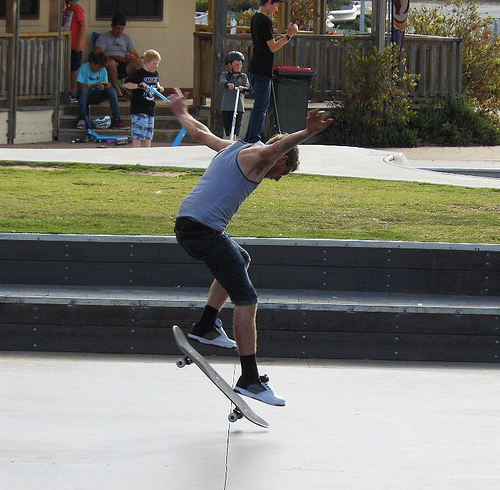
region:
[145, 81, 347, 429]
person on a skateboard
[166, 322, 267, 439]
skateboard made of wood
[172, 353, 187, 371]
a white skateboard wheel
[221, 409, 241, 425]
a white skateboard wheel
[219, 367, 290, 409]
black and white shoe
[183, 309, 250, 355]
black and white shoe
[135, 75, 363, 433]
person wearing grey tank top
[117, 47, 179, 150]
child with blonde hair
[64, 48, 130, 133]
child wearing blue shirt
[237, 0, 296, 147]
child wearing black shirt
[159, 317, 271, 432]
full sized black skateboard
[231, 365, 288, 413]
black and white skate shoes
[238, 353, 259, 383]
black mid length socks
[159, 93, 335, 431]
young man on a skateboard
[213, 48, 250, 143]
young boy with a scooter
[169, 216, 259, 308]
blue jean shorts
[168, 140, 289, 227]
light blue tank top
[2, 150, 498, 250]
green grassy area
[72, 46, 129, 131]
young boy sitting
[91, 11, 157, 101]
father on his phone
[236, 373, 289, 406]
Pair of black and white sneakers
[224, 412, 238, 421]
Round white wheel on skateboard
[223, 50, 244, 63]
Kids black safety helmet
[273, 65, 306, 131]
Garbage can with red lid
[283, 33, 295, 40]
Black watch on mans arm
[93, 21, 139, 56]
Man in grey shirt sitting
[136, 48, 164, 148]
Boy in shorts riding blue scooter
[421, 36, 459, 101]
Wood porch safety rail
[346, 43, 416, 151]
Small green shrub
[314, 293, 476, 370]
Grey and black concrete grind wall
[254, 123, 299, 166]
person has brown hair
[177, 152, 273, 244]
boy wears grey tank top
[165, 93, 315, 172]
boy has arms out for balance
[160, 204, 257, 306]
boy has black shorts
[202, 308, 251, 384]
boy has black socks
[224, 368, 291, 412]
boy has white shoes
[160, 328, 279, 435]
boy has black skateboard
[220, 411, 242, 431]
white wheels on skateboard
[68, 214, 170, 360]
dark blue wall behind boy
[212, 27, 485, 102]
grey fence on building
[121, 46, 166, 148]
Boy is wearing a black shirt.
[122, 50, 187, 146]
Boy is holding a blue scooter.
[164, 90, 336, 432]
Man is skateboarding.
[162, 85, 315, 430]
Man is jumping in the air.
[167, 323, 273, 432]
Skateboard is off the ground.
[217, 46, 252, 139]
Boy is wearing a helmet.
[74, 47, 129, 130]
Boy is looking at an electronic device.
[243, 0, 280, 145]
Young man wearing a black shirt.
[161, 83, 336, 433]
Man is wearing shorts.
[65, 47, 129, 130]
Boy is sitting down.